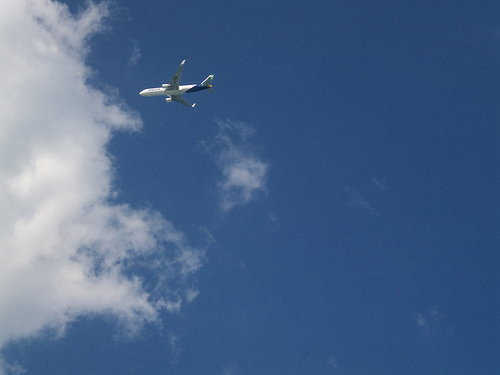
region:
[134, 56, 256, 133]
the plane is flying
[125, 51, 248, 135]
the plane is white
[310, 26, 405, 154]
the sky is blue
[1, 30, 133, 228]
the clouds are white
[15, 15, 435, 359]
the sky is cloudy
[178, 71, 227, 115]
the tail is blue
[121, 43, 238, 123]
the plane is facing left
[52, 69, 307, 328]
there are two clouds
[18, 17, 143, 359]
the cloud is large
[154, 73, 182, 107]
the plane has two engines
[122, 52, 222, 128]
plane against a dark blue sky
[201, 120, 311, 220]
wispy cloud with denser center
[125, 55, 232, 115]
blue paint on rear of plane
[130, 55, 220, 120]
sleek and minimal design of plane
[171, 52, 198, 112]
white winglets pointing upwards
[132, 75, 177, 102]
engines parallel with nose of plane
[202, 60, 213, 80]
lighter blue tip of tail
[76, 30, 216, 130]
plane headed into a cloud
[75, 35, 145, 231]
curved and jagged edge of cloud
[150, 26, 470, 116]
cloudless sky behind plane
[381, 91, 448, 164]
part of the sky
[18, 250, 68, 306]
part of a white cloud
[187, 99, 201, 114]
tip of the right wing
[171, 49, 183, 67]
tip of a left wing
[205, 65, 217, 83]
part of a tail wing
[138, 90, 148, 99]
tip of a plane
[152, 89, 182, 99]
bottom of a plane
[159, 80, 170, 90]
part of a left engine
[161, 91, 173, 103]
part of a right engine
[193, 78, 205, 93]
blue part of the plane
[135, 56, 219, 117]
airplane high up in the sky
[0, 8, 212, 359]
a big fluffy cloud in front of the airplane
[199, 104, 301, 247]
little wispy cloud behind the airplane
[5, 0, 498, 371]
intense blue sky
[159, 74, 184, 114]
two engines on a jet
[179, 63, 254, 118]
airplane tail decorated blue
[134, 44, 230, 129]
an airplane with a diagonal paint job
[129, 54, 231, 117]
a white airplane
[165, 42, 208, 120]
ends of the wings are bent upwards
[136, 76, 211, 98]
lots of tiny windows on a plane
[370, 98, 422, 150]
part of the sky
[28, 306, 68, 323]
part of a white cloud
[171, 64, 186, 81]
part of a left wing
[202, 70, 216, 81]
part of the tail wing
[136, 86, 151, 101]
tip of a plane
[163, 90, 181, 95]
bottom of a plane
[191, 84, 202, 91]
blue part of the plane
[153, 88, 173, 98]
white part of the plane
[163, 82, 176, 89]
left engine of the plane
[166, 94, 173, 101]
right engine of the plane